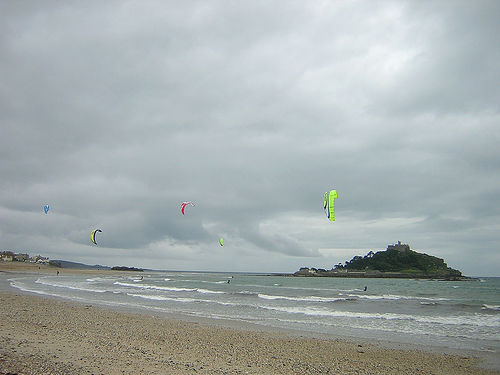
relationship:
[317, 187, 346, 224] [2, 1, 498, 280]
kite in sky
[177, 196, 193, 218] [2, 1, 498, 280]
kite in sky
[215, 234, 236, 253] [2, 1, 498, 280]
kite in sky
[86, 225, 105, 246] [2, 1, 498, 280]
kite in sky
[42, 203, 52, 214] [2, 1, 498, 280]
kite in sky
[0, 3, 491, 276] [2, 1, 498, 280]
clouds in sky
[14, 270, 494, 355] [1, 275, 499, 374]
waves on beach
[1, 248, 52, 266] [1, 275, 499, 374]
buildings near beach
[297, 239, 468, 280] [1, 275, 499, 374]
mountains on beach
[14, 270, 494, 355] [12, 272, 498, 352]
waves in water